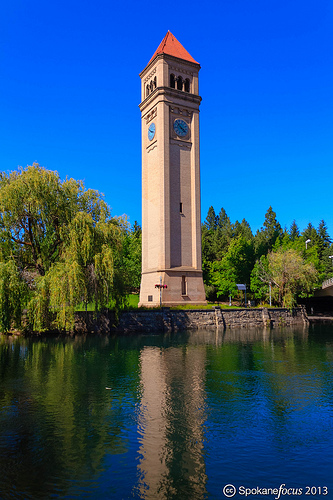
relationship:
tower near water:
[137, 30, 211, 307] [1, 318, 332, 498]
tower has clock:
[137, 30, 211, 307] [173, 118, 191, 138]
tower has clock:
[137, 30, 211, 307] [144, 123, 157, 142]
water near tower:
[1, 318, 332, 498] [137, 30, 211, 307]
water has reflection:
[1, 318, 332, 498] [138, 347, 211, 499]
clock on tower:
[173, 118, 191, 138] [137, 30, 211, 307]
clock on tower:
[144, 123, 157, 142] [137, 30, 211, 307]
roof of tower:
[135, 30, 201, 77] [137, 30, 211, 307]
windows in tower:
[169, 74, 192, 92] [137, 30, 211, 307]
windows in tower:
[145, 75, 159, 94] [137, 30, 211, 307]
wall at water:
[71, 306, 312, 335] [1, 318, 332, 498]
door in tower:
[181, 275, 187, 299] [137, 30, 211, 307]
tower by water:
[137, 30, 211, 307] [1, 318, 332, 498]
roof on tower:
[135, 30, 201, 77] [137, 30, 211, 307]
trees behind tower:
[0, 163, 332, 334] [137, 30, 211, 307]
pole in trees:
[303, 238, 311, 250] [0, 163, 332, 334]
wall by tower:
[71, 306, 312, 335] [137, 30, 211, 307]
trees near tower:
[0, 163, 332, 334] [137, 30, 211, 307]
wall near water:
[71, 306, 312, 335] [1, 318, 332, 498]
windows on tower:
[169, 74, 192, 92] [137, 30, 211, 307]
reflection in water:
[138, 347, 211, 499] [1, 318, 332, 498]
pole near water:
[303, 238, 311, 250] [1, 318, 332, 498]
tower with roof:
[137, 30, 211, 307] [135, 30, 201, 77]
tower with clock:
[137, 30, 211, 307] [144, 123, 157, 142]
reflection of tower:
[138, 347, 211, 499] [137, 30, 211, 307]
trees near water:
[0, 163, 332, 334] [1, 318, 332, 498]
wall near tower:
[71, 306, 312, 335] [137, 30, 211, 307]